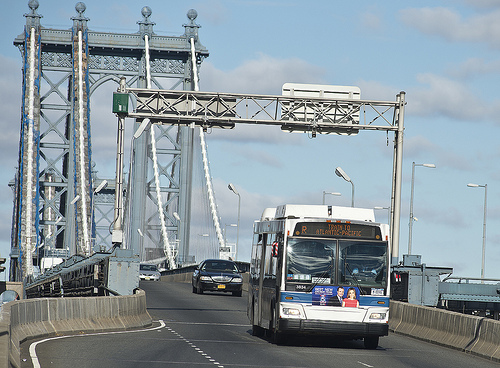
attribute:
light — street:
[465, 179, 487, 199]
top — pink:
[343, 297, 358, 308]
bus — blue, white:
[248, 202, 395, 341]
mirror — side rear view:
[269, 234, 281, 258]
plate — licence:
[316, 276, 353, 320]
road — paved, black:
[20, 279, 497, 364]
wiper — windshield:
[331, 259, 361, 290]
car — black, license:
[189, 252, 247, 292]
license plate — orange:
[216, 284, 226, 291]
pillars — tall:
[128, 153, 243, 285]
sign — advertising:
[310, 284, 363, 306]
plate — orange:
[214, 280, 230, 290]